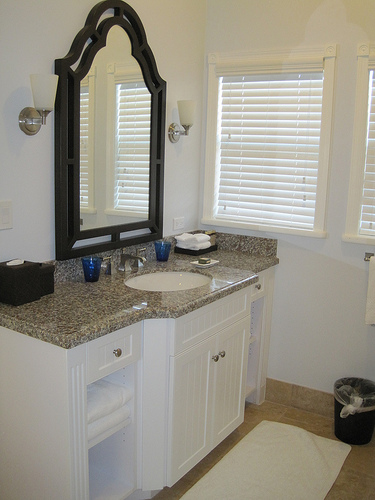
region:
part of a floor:
[353, 466, 364, 484]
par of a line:
[269, 403, 281, 414]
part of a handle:
[216, 358, 235, 373]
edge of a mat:
[272, 408, 295, 446]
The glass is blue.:
[148, 231, 176, 267]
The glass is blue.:
[73, 251, 107, 287]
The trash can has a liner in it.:
[329, 359, 374, 452]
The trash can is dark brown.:
[325, 362, 374, 448]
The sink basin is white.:
[96, 236, 217, 304]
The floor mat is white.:
[148, 410, 359, 498]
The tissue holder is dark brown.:
[0, 249, 49, 314]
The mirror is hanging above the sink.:
[15, 0, 216, 308]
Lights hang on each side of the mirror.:
[14, 1, 201, 266]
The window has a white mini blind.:
[194, 30, 339, 250]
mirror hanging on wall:
[34, 5, 199, 260]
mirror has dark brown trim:
[38, 0, 185, 266]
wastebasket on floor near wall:
[313, 353, 371, 454]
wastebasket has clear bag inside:
[328, 367, 373, 446]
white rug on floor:
[180, 416, 354, 494]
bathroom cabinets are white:
[5, 265, 278, 491]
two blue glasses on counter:
[71, 233, 194, 280]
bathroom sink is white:
[94, 237, 223, 299]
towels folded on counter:
[170, 223, 220, 262]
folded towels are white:
[167, 215, 215, 268]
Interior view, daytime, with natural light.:
[0, 1, 371, 493]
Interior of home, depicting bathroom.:
[2, 3, 370, 495]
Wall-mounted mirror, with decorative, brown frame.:
[58, 11, 166, 241]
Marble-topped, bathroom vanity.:
[4, 234, 299, 479]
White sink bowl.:
[131, 266, 210, 297]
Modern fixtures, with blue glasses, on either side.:
[81, 240, 179, 281]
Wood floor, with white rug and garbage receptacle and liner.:
[244, 367, 364, 492]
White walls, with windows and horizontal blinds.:
[226, 13, 368, 273]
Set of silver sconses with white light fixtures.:
[9, 60, 194, 139]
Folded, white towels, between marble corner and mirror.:
[174, 227, 210, 258]